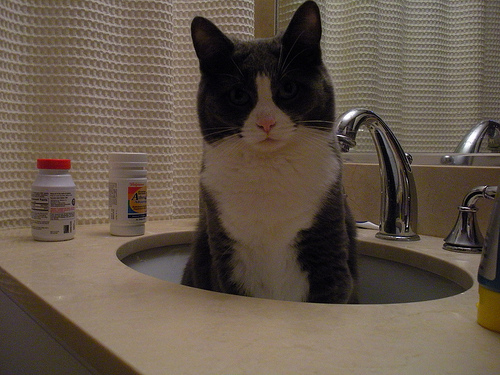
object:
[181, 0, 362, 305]
cat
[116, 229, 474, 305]
sink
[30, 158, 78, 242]
bottles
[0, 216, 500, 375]
counter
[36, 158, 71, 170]
lid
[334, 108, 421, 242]
faucet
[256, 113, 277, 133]
nose